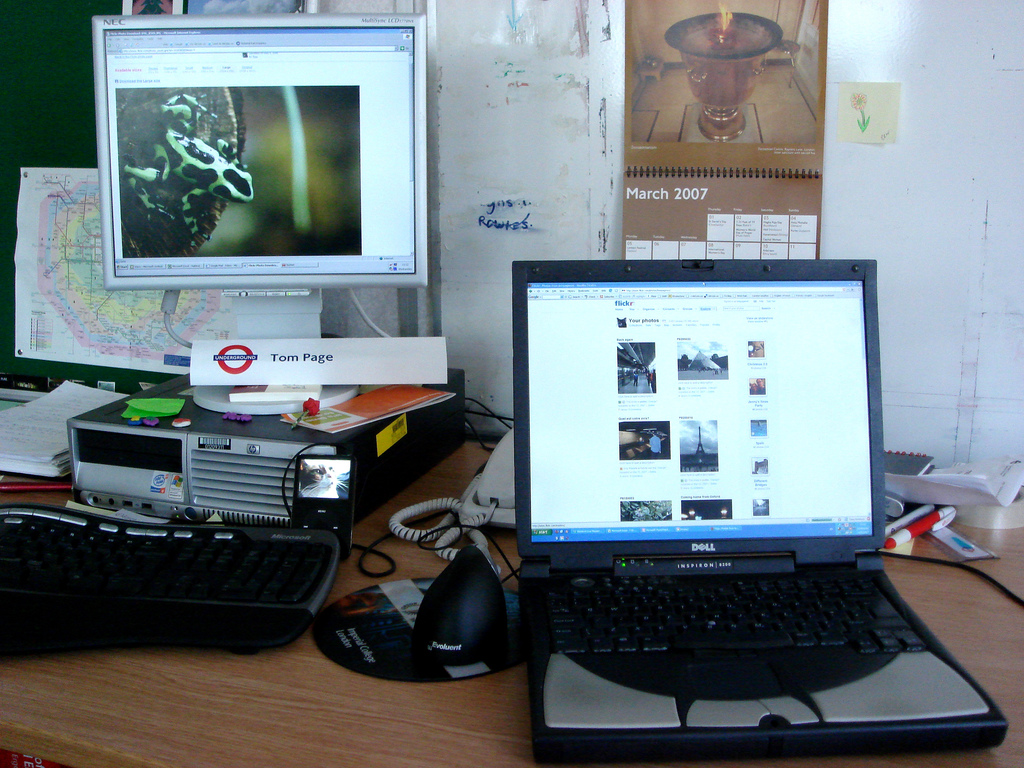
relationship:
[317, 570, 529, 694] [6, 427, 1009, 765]
mouse pad sits on desk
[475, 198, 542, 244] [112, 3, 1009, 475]
note scribbled on wall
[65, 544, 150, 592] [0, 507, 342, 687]
keys on a keyboard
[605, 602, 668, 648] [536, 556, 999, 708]
keys on a keyboard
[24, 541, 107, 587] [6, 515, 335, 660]
keys on a keyboard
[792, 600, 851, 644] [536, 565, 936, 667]
keys on a keyboard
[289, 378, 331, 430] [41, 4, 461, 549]
flower on computer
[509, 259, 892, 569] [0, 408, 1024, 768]
monitor on desk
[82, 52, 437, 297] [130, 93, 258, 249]
monitor displays frog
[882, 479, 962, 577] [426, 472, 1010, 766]
pens on desk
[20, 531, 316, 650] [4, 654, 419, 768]
keyboard on desk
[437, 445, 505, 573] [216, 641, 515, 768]
phone on desk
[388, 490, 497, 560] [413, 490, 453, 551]
cord white phone cord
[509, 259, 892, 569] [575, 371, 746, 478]
monitor of a black laptop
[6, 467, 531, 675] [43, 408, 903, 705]
oddsandends cover desk